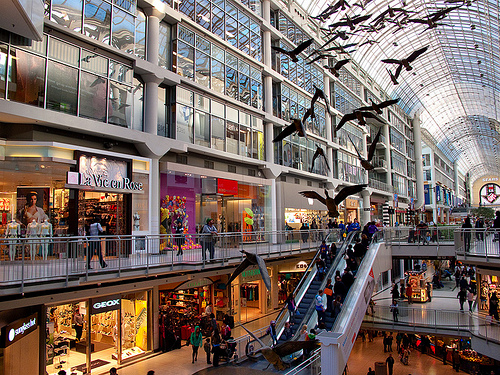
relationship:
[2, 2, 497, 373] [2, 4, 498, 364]
shopping mall in picture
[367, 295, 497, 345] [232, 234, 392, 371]
railing around walkway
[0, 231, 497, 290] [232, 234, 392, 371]
railing around walkway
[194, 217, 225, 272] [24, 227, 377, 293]
woman leans over railing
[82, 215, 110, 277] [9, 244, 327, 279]
person walks on elevated walkway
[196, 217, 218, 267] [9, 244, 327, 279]
woman walks on elevated walkway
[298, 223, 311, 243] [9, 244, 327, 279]
person walks on elevated walkway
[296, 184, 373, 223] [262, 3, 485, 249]
birds are on mobile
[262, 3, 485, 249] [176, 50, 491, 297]
mobile in mall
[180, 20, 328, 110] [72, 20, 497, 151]
sky shines through atrium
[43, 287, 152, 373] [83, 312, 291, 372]
store on first floor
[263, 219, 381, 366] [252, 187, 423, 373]
people are on escalator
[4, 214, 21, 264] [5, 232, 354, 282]
mannequin on floor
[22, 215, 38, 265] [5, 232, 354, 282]
mannequin on floor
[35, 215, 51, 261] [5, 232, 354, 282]
mannequins on floor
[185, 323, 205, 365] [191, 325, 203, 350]
customer in green hoodie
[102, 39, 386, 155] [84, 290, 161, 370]
reflection in mirror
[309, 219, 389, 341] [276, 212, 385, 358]
people in escalators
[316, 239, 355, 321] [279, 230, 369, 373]
people on escalator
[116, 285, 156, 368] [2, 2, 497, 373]
window on shopping mall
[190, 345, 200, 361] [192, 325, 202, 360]
pants on woman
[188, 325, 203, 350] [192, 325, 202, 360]
green hoodie on woman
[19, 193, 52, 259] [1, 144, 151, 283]
mannequins in window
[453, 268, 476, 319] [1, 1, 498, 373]
shopper walking in mall